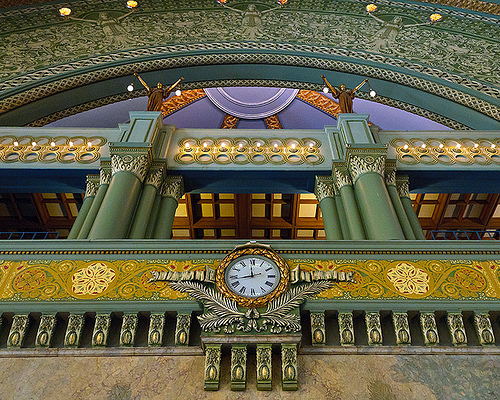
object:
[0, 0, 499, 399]
arch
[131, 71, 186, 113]
brass statue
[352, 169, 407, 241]
columns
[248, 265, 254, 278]
black hands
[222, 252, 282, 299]
frame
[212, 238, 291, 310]
clock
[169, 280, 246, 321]
leaves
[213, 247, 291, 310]
gold trim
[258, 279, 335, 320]
leaves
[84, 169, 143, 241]
columns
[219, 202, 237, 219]
panels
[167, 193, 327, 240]
ceiling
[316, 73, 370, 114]
statue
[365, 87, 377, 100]
lights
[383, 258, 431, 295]
figures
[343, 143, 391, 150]
trim